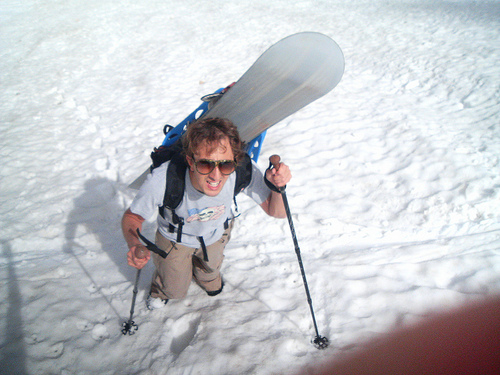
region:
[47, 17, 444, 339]
a man with a snowboard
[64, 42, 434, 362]
a man standing on the snow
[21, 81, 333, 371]
a man walking on the snow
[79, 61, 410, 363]
a man with a snowboard on his back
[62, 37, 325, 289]
a man wearing sunglasses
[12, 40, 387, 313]
a man wearing a blue shirt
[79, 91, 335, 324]
a man wearing pants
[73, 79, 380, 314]
a man wearing shirt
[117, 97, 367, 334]
a man with long hair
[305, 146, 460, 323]
ground covered in snow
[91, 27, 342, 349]
man with snow board looking up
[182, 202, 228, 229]
skull design on t-shirt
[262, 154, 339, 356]
black ski pole with brown knob handle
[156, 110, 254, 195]
man with sunglasses on face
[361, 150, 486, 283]
foot prints and tracks in the snow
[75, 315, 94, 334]
track made from ski pole in the snow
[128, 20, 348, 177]
large grey snowboard on man's back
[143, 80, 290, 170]
blue equipment carrier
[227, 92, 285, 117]
striped design on snowboard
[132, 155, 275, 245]
light blue t-shirt and back pack straps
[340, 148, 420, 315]
the snow is white and clear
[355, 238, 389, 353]
the snow is white and clear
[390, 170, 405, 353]
the snow is white and clear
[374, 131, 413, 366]
the snow is white and clear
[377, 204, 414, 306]
the snow is white and clear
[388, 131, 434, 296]
the snow is white and clear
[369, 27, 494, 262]
white snow on the ground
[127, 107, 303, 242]
a man wearing sunglasses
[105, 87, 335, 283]
a man wearing a grey shirt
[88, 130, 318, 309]
a man wearing a tshirt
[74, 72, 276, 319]
a man wearing tan pants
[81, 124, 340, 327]
a man wearing a backpack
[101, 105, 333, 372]
a man holding poles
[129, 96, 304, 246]
a man with brown hair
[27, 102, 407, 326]
a man walking on snow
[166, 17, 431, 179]
a snowboard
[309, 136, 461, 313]
the snow is white and clear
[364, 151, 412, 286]
the snow is white and clear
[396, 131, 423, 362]
the snow is white and clear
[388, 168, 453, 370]
the snow is white and clear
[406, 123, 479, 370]
the snow is white and clear